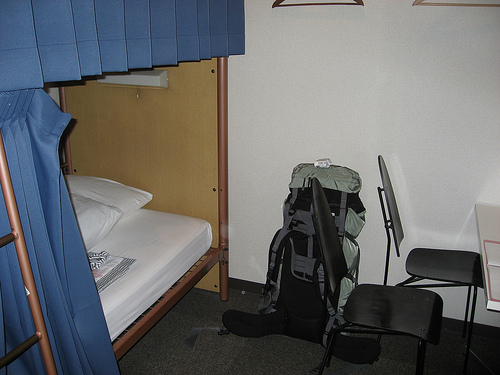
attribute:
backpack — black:
[218, 158, 382, 365]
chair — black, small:
[309, 177, 444, 375]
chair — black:
[376, 154, 485, 366]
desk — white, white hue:
[475, 202, 500, 312]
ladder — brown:
[0, 133, 59, 375]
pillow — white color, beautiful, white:
[63, 173, 153, 219]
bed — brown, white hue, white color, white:
[87, 207, 214, 343]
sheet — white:
[86, 208, 213, 343]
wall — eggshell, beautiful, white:
[229, 0, 499, 329]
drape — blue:
[1, 88, 122, 374]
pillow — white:
[69, 191, 124, 251]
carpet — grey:
[117, 286, 499, 374]